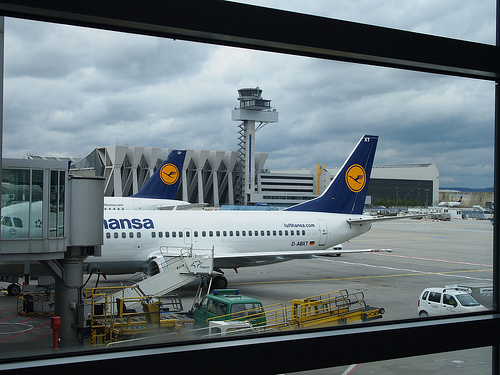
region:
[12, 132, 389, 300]
the plane is white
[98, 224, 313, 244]
the plane has many windows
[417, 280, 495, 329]
the van is white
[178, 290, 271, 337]
the van is green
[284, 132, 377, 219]
the tail on the plane is blue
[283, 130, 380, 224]
the tail of the plane has a logo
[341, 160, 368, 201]
the logo is yellow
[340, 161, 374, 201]
the logo is round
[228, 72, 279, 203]
the tower is tall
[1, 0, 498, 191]
the sky looks stormy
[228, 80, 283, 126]
an airport watch tower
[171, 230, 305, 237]
windows on the side of a plae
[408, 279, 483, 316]
a white vehicle in a parking lot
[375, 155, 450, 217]
an air plane hanger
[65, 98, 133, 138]
clouds in the sky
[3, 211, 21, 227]
windows on a plane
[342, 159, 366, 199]
symbol on the tail of a plane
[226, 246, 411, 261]
wing on a plane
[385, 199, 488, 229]
vehicles in a parking lot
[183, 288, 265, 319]
green van in a parking lot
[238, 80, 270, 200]
CONTROLLER TOWER OVERLOOKING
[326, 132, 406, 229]
THE TAIL OF THE PLANE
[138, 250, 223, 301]
STAIRWAY TO THE PLANE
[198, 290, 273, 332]
EMERGENCY VEHICLE IS CLOSE BY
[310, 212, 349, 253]
THE DOOR IS CLOSED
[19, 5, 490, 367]
THIS VIEW IS FROM A WINDOW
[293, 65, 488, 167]
IT'S A CLOUDY DAY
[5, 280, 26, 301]
THE WHEELS ARE DOWN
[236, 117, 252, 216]
TALL STAIRWELL TO THE TOWER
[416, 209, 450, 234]
CONES ON THE GROUND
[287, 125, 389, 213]
blue tail with yellow circle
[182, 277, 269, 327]
green van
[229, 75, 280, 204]
control tower at an airport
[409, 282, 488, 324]
white compact car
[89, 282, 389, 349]
yellow luggage loaders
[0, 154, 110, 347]
bridge to airport terminal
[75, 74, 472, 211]
grey airport terminal with many windows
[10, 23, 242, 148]
sky full of dark clouds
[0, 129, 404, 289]
white airliner with blue tail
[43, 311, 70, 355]
red meter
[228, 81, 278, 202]
An air traffic control tower at an airport.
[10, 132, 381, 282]
Two planes at the airport.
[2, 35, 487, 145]
Stormy clouds in the sky.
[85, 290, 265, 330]
A green airport luggage truck.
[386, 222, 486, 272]
Grey airport tarmac.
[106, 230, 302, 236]
Several windows on the airplane.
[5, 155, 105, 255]
The loading Jetway.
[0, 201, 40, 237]
The airplane's cockpit.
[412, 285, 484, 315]
A white airport vehicle.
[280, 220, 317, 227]
The website address for the airline.